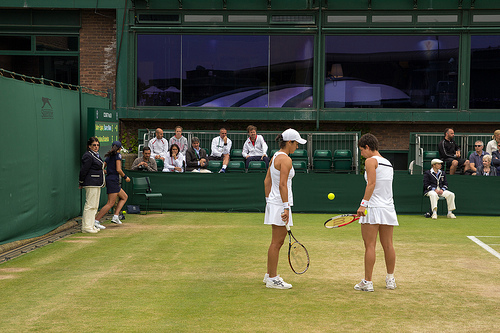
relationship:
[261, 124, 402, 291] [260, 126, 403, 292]
ladies playing tennis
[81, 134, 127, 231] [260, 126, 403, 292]
ladies playing tennis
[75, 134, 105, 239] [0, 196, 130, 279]
lady standing in sideline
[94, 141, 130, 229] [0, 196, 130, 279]
ladies standing in sideline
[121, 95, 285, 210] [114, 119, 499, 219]
people watching in stands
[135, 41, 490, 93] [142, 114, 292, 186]
windows behind bleachers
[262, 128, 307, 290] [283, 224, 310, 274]
ladies holding tennis racket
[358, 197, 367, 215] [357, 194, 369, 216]
sweatband on wrist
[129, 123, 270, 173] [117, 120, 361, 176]
specatators sitting in gallery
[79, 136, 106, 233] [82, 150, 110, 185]
lady in jacket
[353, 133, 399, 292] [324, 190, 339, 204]
lady bouncing ball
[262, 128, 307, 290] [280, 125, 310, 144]
ladies wearing cap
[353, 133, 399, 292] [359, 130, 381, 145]
lady has hair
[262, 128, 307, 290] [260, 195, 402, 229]
ladies wearing dresses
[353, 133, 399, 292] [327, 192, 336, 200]
lady bouncing ball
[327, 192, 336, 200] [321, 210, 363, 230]
ball on racket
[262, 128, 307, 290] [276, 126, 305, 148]
ladies wearing cap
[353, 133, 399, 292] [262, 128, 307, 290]
lady playing ladies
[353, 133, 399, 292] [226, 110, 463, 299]
lady playing tennis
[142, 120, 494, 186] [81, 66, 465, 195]
people in background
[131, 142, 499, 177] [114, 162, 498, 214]
seating in front of screen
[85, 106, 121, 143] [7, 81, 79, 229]
scoreboard by wall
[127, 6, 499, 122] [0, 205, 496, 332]
glass wall overlooking tennis court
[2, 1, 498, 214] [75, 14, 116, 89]
building made of bricks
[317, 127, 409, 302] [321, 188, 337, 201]
lady with ball